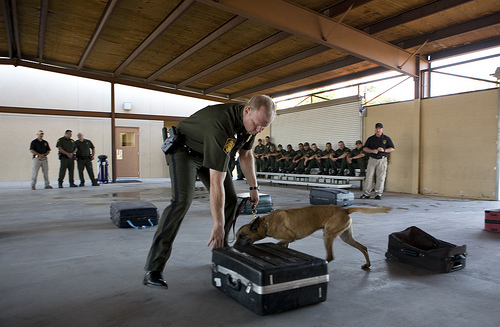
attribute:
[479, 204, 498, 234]
suitcase — edge, red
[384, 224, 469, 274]
suitcase — black, open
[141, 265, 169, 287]
shoe — black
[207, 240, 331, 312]
case — black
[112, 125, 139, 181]
door — peach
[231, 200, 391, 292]
brown dog — is brown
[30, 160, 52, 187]
pants — tan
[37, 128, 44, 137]
hat — white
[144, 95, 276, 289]
officer — police